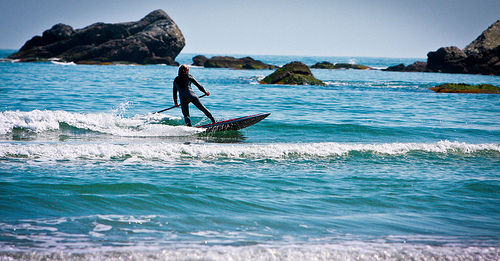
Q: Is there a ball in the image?
A: No, there are no balls.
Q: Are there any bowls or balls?
A: No, there are no balls or bowls.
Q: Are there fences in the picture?
A: No, there are no fences.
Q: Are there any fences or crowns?
A: No, there are no fences or crowns.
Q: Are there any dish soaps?
A: No, there are no dish soaps.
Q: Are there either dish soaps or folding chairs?
A: No, there are no dish soaps or folding chairs.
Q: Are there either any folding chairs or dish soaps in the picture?
A: No, there are no dish soaps or folding chairs.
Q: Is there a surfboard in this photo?
A: Yes, there is a surfboard.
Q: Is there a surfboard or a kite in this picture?
A: Yes, there is a surfboard.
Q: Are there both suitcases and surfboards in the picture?
A: No, there is a surfboard but no suitcases.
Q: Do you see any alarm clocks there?
A: No, there are no alarm clocks.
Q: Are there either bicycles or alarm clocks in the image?
A: No, there are no alarm clocks or bicycles.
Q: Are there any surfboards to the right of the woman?
A: Yes, there is a surfboard to the right of the woman.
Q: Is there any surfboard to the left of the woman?
A: No, the surfboard is to the right of the woman.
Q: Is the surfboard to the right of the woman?
A: Yes, the surfboard is to the right of the woman.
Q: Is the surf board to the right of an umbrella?
A: No, the surf board is to the right of the woman.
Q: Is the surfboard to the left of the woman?
A: No, the surfboard is to the right of the woman.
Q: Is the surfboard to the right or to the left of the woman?
A: The surfboard is to the right of the woman.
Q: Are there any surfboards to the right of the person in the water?
A: Yes, there is a surfboard to the right of the person.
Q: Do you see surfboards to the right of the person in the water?
A: Yes, there is a surfboard to the right of the person.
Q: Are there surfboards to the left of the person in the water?
A: No, the surfboard is to the right of the person.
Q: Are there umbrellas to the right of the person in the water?
A: No, there is a surfboard to the right of the person.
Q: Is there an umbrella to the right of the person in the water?
A: No, there is a surfboard to the right of the person.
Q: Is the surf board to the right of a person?
A: Yes, the surf board is to the right of a person.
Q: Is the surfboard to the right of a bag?
A: No, the surfboard is to the right of a person.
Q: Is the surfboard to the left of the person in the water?
A: No, the surfboard is to the right of the person.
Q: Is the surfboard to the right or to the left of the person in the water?
A: The surfboard is to the right of the person.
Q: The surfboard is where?
A: The surfboard is on the water.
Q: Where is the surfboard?
A: The surfboard is on the water.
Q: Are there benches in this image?
A: No, there are no benches.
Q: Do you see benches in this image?
A: No, there are no benches.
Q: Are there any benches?
A: No, there are no benches.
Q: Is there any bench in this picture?
A: No, there are no benches.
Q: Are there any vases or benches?
A: No, there are no benches or vases.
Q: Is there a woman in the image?
A: Yes, there is a woman.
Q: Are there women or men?
A: Yes, there is a woman.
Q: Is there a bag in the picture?
A: No, there are no bags.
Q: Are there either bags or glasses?
A: No, there are no bags or glasses.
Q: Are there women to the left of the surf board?
A: Yes, there is a woman to the left of the surf board.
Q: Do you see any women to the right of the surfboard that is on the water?
A: No, the woman is to the left of the surfboard.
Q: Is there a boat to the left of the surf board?
A: No, there is a woman to the left of the surf board.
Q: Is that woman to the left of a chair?
A: No, the woman is to the left of the surfboard.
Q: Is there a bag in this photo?
A: No, there are no bags.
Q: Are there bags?
A: No, there are no bags.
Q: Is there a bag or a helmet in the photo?
A: No, there are no bags or helmets.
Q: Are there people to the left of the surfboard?
A: Yes, there is a person to the left of the surfboard.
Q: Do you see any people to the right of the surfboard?
A: No, the person is to the left of the surfboard.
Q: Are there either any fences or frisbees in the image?
A: No, there are no fences or frisbees.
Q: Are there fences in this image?
A: No, there are no fences.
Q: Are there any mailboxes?
A: No, there are no mailboxes.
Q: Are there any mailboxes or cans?
A: No, there are no mailboxes or cans.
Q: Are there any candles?
A: No, there are no candles.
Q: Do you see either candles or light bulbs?
A: No, there are no candles or light bulbs.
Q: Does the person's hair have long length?
A: Yes, the hair is long.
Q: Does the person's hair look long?
A: Yes, the hair is long.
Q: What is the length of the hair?
A: The hair is long.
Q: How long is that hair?
A: The hair is long.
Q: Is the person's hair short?
A: No, the hair is long.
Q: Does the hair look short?
A: No, the hair is long.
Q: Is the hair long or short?
A: The hair is long.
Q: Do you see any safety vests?
A: No, there are no safety vests.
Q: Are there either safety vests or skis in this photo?
A: No, there are no safety vests or skis.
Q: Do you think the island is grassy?
A: Yes, the island is grassy.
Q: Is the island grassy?
A: Yes, the island is grassy.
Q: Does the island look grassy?
A: Yes, the island is grassy.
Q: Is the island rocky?
A: No, the island is grassy.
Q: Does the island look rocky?
A: No, the island is grassy.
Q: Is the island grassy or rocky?
A: The island is grassy.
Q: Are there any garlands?
A: No, there are no garlands.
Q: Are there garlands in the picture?
A: No, there are no garlands.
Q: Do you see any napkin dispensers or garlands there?
A: No, there are no garlands or napkin dispensers.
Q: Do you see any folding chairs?
A: No, there are no folding chairs.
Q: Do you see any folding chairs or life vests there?
A: No, there are no folding chairs or life vests.